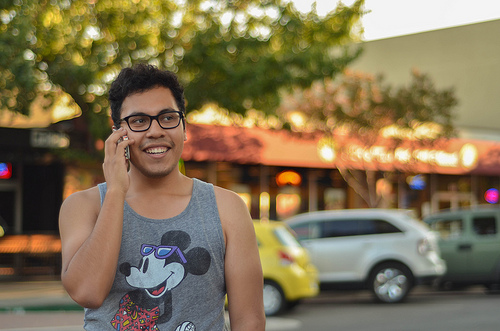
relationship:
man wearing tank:
[58, 60, 266, 330] [83, 177, 227, 331]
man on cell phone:
[58, 60, 266, 330] [112, 130, 134, 163]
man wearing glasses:
[58, 60, 266, 330] [121, 110, 185, 133]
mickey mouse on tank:
[110, 230, 211, 331] [83, 177, 227, 331]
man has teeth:
[58, 60, 266, 330] [142, 147, 169, 155]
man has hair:
[58, 60, 266, 330] [108, 65, 187, 129]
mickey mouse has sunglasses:
[110, 230, 211, 331] [139, 241, 190, 265]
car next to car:
[221, 218, 320, 318] [278, 205, 446, 305]